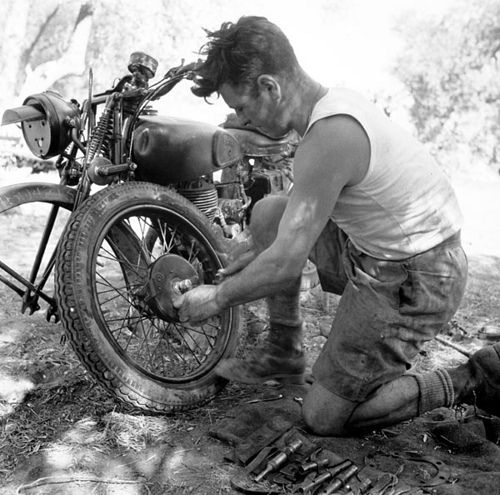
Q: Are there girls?
A: No, there are no girls.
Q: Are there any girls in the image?
A: No, there are no girls.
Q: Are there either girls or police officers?
A: No, there are no girls or police officers.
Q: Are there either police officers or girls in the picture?
A: No, there are no girls or police officers.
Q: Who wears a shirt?
A: The man wears a shirt.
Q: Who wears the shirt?
A: The man wears a shirt.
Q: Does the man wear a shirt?
A: Yes, the man wears a shirt.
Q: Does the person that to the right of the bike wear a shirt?
A: Yes, the man wears a shirt.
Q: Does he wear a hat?
A: No, the man wears a shirt.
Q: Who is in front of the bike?
A: The man is in front of the bike.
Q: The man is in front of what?
A: The man is in front of the bike.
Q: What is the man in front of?
A: The man is in front of the bike.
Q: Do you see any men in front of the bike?
A: Yes, there is a man in front of the bike.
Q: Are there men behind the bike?
A: No, the man is in front of the bike.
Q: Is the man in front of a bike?
A: Yes, the man is in front of a bike.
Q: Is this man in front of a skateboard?
A: No, the man is in front of a bike.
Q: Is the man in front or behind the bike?
A: The man is in front of the bike.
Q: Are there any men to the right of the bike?
A: Yes, there is a man to the right of the bike.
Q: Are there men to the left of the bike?
A: No, the man is to the right of the bike.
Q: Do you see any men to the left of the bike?
A: No, the man is to the right of the bike.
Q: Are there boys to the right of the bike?
A: No, there is a man to the right of the bike.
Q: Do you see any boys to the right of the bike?
A: No, there is a man to the right of the bike.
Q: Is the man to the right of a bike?
A: Yes, the man is to the right of a bike.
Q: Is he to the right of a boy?
A: No, the man is to the right of a bike.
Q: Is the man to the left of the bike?
A: No, the man is to the right of the bike.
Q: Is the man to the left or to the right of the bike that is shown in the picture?
A: The man is to the right of the bike.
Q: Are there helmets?
A: No, there are no helmets.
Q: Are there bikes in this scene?
A: Yes, there is a bike.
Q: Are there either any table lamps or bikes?
A: Yes, there is a bike.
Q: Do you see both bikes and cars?
A: No, there is a bike but no cars.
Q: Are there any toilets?
A: No, there are no toilets.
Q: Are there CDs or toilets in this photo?
A: No, there are no toilets or cds.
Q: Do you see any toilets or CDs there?
A: No, there are no toilets or cds.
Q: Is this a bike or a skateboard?
A: This is a bike.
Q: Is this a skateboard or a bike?
A: This is a bike.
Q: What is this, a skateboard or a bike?
A: This is a bike.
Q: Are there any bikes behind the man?
A: Yes, there is a bike behind the man.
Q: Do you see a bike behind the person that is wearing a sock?
A: Yes, there is a bike behind the man.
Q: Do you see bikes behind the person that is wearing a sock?
A: Yes, there is a bike behind the man.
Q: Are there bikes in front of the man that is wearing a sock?
A: No, the bike is behind the man.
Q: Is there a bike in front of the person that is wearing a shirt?
A: No, the bike is behind the man.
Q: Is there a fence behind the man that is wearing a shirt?
A: No, there is a bike behind the man.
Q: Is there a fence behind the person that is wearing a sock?
A: No, there is a bike behind the man.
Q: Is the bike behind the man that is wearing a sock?
A: Yes, the bike is behind the man.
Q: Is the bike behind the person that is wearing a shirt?
A: Yes, the bike is behind the man.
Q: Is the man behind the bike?
A: No, the bike is behind the man.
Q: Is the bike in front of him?
A: No, the bike is behind a man.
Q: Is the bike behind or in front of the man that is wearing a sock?
A: The bike is behind the man.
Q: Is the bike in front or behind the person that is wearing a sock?
A: The bike is behind the man.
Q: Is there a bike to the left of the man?
A: Yes, there is a bike to the left of the man.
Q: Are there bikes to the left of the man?
A: Yes, there is a bike to the left of the man.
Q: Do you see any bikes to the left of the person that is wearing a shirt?
A: Yes, there is a bike to the left of the man.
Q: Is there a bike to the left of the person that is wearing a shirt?
A: Yes, there is a bike to the left of the man.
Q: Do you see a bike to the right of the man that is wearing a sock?
A: No, the bike is to the left of the man.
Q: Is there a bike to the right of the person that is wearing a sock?
A: No, the bike is to the left of the man.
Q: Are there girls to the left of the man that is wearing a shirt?
A: No, there is a bike to the left of the man.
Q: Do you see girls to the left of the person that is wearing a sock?
A: No, there is a bike to the left of the man.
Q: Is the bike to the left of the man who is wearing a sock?
A: Yes, the bike is to the left of the man.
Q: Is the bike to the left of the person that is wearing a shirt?
A: Yes, the bike is to the left of the man.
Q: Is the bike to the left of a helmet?
A: No, the bike is to the left of the man.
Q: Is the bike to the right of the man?
A: No, the bike is to the left of the man.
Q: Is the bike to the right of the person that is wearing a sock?
A: No, the bike is to the left of the man.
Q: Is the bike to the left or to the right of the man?
A: The bike is to the left of the man.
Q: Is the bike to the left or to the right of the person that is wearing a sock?
A: The bike is to the left of the man.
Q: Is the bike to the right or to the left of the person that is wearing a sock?
A: The bike is to the left of the man.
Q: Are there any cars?
A: No, there are no cars.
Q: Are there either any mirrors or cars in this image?
A: No, there are no cars or mirrors.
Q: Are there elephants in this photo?
A: No, there are no elephants.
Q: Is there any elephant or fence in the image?
A: No, there are no elephants or fences.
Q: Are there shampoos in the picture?
A: No, there are no shampoos.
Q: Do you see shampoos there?
A: No, there are no shampoos.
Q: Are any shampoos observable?
A: No, there are no shampoos.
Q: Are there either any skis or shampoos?
A: No, there are no shampoos or skis.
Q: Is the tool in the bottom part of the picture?
A: Yes, the tool is in the bottom of the image.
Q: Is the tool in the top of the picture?
A: No, the tool is in the bottom of the image.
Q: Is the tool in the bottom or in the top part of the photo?
A: The tool is in the bottom of the image.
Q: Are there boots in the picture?
A: Yes, there are boots.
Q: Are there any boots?
A: Yes, there are boots.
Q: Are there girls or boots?
A: Yes, there are boots.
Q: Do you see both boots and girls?
A: No, there are boots but no girls.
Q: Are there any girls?
A: No, there are no girls.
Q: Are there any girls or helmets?
A: No, there are no girls or helmets.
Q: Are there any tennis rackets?
A: No, there are no tennis rackets.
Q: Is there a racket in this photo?
A: No, there are no rackets.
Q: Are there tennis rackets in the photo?
A: No, there are no tennis rackets.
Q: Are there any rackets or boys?
A: No, there are no rackets or boys.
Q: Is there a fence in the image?
A: No, there are no fences.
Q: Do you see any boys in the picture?
A: No, there are no boys.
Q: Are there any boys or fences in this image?
A: No, there are no boys or fences.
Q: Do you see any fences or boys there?
A: No, there are no boys or fences.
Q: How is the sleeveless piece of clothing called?
A: The clothing item is a shirt.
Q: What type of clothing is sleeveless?
A: The clothing is a shirt.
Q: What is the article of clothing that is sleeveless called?
A: The clothing item is a shirt.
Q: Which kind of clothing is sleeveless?
A: The clothing is a shirt.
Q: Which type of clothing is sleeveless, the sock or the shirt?
A: The shirt is sleeveless.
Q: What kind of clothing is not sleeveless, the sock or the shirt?
A: The sock is not sleeveless.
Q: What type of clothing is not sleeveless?
A: The clothing is a sock.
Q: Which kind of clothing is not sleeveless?
A: The clothing is a sock.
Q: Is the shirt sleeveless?
A: Yes, the shirt is sleeveless.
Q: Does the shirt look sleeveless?
A: Yes, the shirt is sleeveless.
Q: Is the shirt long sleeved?
A: No, the shirt is sleeveless.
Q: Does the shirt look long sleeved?
A: No, the shirt is sleeveless.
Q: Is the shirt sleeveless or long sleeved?
A: The shirt is sleeveless.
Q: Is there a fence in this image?
A: No, there are no fences.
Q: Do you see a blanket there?
A: Yes, there is a blanket.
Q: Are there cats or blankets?
A: Yes, there is a blanket.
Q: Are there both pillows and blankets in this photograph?
A: No, there is a blanket but no pillows.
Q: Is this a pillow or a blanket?
A: This is a blanket.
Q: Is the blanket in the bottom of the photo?
A: Yes, the blanket is in the bottom of the image.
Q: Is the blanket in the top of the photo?
A: No, the blanket is in the bottom of the image.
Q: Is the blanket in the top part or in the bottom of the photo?
A: The blanket is in the bottom of the image.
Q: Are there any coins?
A: No, there are no coins.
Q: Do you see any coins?
A: No, there are no coins.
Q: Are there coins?
A: No, there are no coins.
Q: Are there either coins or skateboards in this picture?
A: No, there are no coins or skateboards.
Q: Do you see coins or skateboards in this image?
A: No, there are no coins or skateboards.